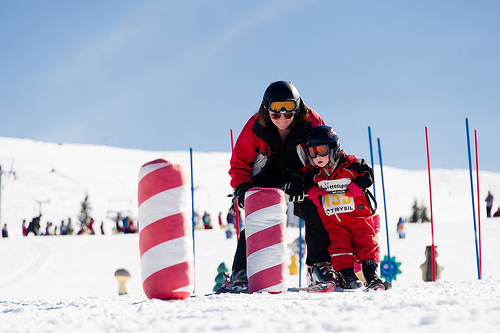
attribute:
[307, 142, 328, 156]
goggles — red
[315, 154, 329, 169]
mouth — open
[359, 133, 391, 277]
pole — skinny, blue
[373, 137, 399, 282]
pole — blue 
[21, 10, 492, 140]
sky — blue , pale 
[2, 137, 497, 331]
snow — white 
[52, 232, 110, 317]
ground — red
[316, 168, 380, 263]
snowsuit — red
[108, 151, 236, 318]
stripes — white , red 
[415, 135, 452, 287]
red pole — skinny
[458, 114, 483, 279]
stick — blue 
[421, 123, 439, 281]
pole — skinny